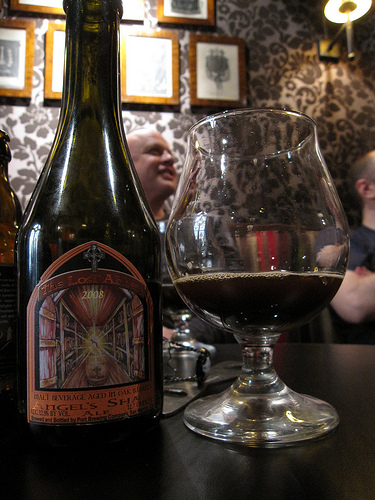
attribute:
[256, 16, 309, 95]
wallpaper — floral, patterned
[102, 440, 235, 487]
table — wooden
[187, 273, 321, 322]
wine — brown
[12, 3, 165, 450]
bottle — glass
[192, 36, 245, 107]
picture — framed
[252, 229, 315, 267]
chair — striped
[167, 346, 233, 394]
bottle opener — metal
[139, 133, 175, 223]
man — smiling